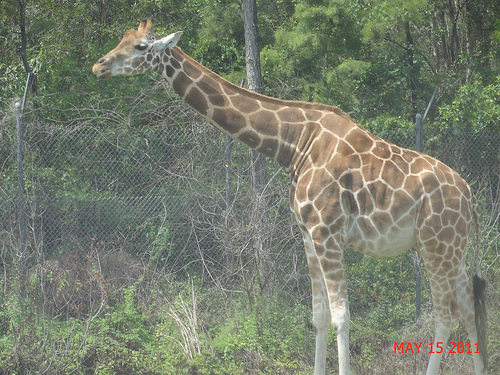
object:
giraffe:
[90, 17, 489, 374]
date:
[391, 341, 481, 354]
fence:
[0, 124, 499, 298]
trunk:
[238, 0, 270, 193]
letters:
[391, 341, 405, 353]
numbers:
[427, 340, 482, 353]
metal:
[14, 122, 128, 233]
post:
[14, 102, 24, 250]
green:
[52, 31, 82, 81]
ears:
[151, 30, 186, 58]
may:
[391, 342, 423, 354]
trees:
[0, 0, 62, 103]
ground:
[0, 344, 499, 374]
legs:
[454, 262, 485, 374]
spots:
[342, 127, 373, 154]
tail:
[467, 191, 493, 374]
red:
[471, 341, 482, 353]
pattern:
[309, 181, 345, 227]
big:
[157, 34, 327, 173]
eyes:
[134, 41, 148, 51]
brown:
[175, 75, 189, 90]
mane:
[173, 45, 346, 118]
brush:
[205, 302, 291, 372]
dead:
[195, 177, 305, 304]